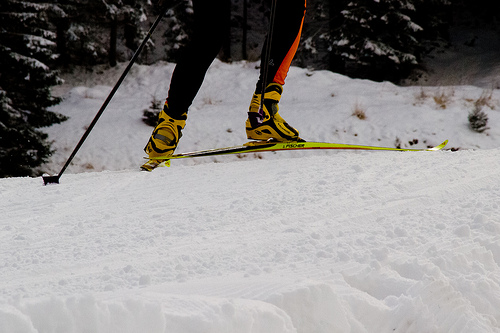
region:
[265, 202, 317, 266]
part of a ground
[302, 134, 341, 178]
part of a slider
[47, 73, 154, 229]
part of a hokker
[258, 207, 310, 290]
part of a snow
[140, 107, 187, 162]
a yellow ski boot on a persons foot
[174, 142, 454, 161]
a yellow ski on a persons foot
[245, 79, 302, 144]
a yellow ski boot on a persons foot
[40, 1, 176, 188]
a ski pole in a persons hand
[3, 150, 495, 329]
snow on a ski course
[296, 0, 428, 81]
a distant pine tree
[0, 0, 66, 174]
a dark green pine tree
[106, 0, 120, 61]
a tree trunk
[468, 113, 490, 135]
a pine cone in the snow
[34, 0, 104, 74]
a pine tree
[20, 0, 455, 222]
A skier's legs in the snow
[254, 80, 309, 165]
Yellow shoes on the feet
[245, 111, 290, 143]
The shoes have black stripes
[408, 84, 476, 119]
Sparse patches of dead grass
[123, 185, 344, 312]
Fluffy white snow on the ground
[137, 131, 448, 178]
A pair of yellow skis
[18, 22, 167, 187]
A black skipole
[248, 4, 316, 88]
Orange and black pants on the man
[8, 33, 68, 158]
Trees behind the man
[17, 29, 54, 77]
White snow on the trees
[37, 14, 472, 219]
person skiing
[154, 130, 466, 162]
thin yellow ski on the snow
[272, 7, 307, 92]
orange stripe running down the leg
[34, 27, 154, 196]
thin black ski pole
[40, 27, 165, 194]
ski pole sticking in the snow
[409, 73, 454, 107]
plants popping out of the snow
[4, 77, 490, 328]
ground is covered in snow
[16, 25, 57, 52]
snow on the trees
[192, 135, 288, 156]
black stripe on the ski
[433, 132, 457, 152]
front end of the ski is bent upwards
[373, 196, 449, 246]
White packed snow on the ground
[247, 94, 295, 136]
Yellow and black snow shoe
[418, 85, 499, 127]
Dead grass above the snow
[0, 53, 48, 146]
White snow on a green tree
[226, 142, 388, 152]
Yellow ski on the snow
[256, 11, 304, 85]
Orange and black snow pants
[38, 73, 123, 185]
Black ski pole on the snow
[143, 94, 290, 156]
Two yellow and black snow shoes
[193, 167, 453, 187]
White snow below a ski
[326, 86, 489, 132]
Dead grass on a hill